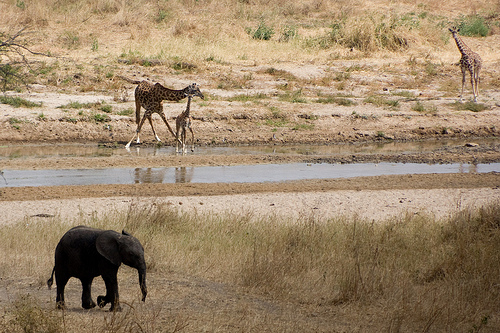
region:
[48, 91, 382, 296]
animals are grazing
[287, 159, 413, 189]
water running through the valley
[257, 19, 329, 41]
plants are green in color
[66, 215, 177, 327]
the elephant si walking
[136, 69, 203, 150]
two giraffs near the watr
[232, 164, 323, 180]
water is brown in color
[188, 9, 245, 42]
the grasses are brown in color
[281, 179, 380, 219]
the floor is muddy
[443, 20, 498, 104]
the giraffe is standing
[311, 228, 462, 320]
the branches are dried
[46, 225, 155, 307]
this is an elephant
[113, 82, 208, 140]
this is a giraffe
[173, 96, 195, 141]
this is a giraffe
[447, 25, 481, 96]
this is a giraffe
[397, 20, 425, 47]
the grass is dry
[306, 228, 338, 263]
the grass is dry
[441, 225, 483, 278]
the grass is dry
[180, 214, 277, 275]
the grass is dry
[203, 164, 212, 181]
this is a pond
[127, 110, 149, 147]
the leg of a giraffe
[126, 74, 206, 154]
giraffe parent and offspring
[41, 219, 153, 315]
elephant on the savanna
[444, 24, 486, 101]
a giraffe on the savanna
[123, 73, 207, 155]
giraffes at a watering hole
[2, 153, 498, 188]
a watering hole in a savanna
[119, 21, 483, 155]
a giraffe family in the wild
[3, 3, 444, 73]
the african savannah at midday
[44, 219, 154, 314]
an elephant roaming in the wild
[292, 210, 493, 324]
tall grass in a savannah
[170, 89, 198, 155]
a baby giraffe in the wild savannah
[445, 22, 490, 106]
giraffe standing next to the water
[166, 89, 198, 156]
giraffe standing next to the water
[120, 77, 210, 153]
giraffe standing next to the water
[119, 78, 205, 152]
baby and mom giraffe standing together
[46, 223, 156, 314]
elephant walking in the grass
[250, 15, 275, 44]
large clump of green grass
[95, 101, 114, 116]
large clump of green grass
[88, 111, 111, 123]
large clump of green grass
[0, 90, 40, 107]
large clump of green grass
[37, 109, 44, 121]
large clump of green grass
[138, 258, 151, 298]
the trunk of an elephant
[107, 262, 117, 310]
this is a leg of an elephant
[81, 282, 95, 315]
this is a leg of an elephant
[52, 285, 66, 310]
this is a leg of an elephant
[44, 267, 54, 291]
this is a tail of an elephant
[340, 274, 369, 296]
the grass is dry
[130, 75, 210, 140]
this is a giraffe and the young one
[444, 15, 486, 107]
this is a giraffe